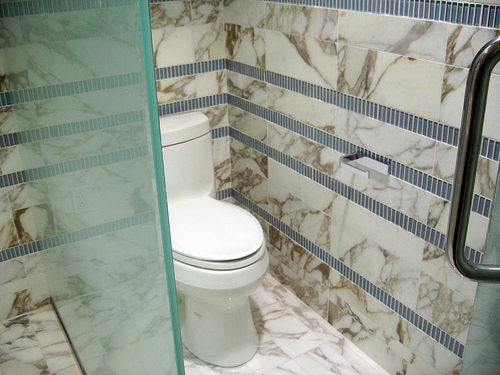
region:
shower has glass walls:
[27, 83, 176, 321]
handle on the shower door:
[460, 40, 498, 325]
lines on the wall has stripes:
[381, 68, 410, 141]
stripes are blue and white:
[358, 88, 412, 125]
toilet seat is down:
[179, 197, 279, 292]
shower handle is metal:
[436, 111, 497, 281]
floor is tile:
[289, 279, 314, 370]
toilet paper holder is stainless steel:
[326, 151, 378, 200]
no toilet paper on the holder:
[339, 138, 405, 200]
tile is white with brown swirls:
[362, 25, 462, 112]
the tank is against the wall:
[146, 111, 218, 202]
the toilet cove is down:
[157, 196, 267, 270]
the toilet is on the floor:
[153, 234, 271, 363]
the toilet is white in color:
[132, 112, 268, 368]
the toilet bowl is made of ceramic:
[152, 230, 267, 362]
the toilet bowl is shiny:
[165, 233, 269, 367]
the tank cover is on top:
[157, 112, 212, 145]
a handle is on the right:
[449, 31, 499, 276]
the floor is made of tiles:
[0, 241, 390, 371]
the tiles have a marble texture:
[2, 258, 394, 370]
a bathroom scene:
[38, 25, 425, 346]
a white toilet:
[123, 107, 275, 364]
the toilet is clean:
[140, 125, 279, 311]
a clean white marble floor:
[165, 253, 377, 374]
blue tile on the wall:
[223, 61, 460, 216]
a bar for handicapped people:
[410, 30, 498, 301]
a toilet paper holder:
[320, 134, 391, 206]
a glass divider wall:
[18, 9, 198, 374]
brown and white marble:
[168, 8, 455, 96]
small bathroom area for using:
[141, 11, 446, 372]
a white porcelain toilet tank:
[155, 113, 215, 198]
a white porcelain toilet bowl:
[170, 246, 272, 368]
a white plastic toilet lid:
[168, 198, 263, 261]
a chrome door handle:
[449, 33, 496, 288]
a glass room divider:
[17, 0, 187, 374]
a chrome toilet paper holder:
[337, 149, 390, 182]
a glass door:
[456, 200, 496, 371]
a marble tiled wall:
[225, 0, 495, 372]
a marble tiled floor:
[0, 270, 390, 370]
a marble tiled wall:
[0, 0, 232, 322]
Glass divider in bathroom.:
[2, 0, 207, 372]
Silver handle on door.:
[442, 38, 498, 288]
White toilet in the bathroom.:
[157, 107, 279, 367]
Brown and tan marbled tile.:
[229, 1, 385, 90]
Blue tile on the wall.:
[157, 62, 229, 82]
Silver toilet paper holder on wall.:
[335, 146, 378, 205]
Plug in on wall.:
[62, 183, 99, 220]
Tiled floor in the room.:
[96, 279, 323, 374]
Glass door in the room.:
[465, 170, 499, 374]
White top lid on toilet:
[158, 111, 218, 145]